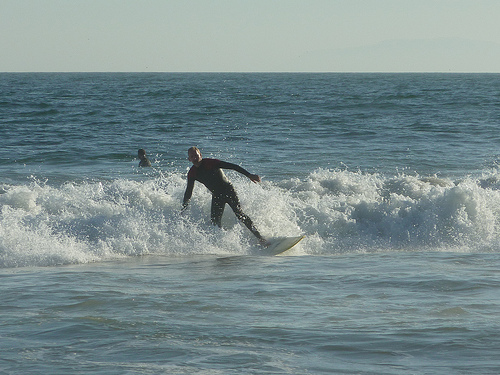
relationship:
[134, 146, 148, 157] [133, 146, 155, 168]
head of person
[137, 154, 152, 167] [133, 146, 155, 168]
shoulders of person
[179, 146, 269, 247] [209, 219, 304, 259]
man standing on surfboard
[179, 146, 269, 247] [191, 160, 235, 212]
man in wetsuit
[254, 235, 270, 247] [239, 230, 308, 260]
foot on surfboard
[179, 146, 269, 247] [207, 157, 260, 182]
man with arm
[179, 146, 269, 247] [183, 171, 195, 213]
man with arm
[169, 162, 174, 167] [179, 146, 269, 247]
water drop behind man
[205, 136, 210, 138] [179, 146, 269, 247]
water drop behind man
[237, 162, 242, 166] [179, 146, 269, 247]
water drop behind man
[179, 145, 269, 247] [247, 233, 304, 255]
man on surfboard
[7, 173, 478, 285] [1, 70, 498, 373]
waves in water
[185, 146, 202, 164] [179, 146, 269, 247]
head of man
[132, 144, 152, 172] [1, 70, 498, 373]
person swimming water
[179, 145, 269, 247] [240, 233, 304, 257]
man riding a surfboard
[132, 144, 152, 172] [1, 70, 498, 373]
person in water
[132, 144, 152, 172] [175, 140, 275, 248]
person behind surfer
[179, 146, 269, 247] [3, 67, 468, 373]
man riding a wave shore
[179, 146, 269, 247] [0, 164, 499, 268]
man surfing in on waves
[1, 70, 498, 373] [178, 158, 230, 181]
water in back of shoulders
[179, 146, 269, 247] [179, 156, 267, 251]
man covered in wetsuit